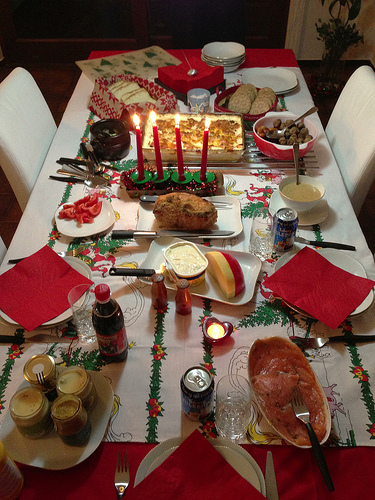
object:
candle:
[133, 115, 147, 182]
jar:
[9, 385, 51, 440]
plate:
[0, 362, 116, 469]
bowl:
[251, 110, 318, 161]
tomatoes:
[59, 206, 76, 219]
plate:
[54, 196, 116, 239]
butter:
[167, 243, 206, 276]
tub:
[163, 240, 209, 289]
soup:
[281, 182, 320, 203]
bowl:
[277, 174, 327, 213]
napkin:
[2, 245, 99, 329]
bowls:
[201, 38, 247, 60]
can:
[180, 365, 214, 425]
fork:
[290, 386, 334, 493]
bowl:
[246, 331, 331, 449]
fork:
[111, 451, 133, 500]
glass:
[215, 372, 254, 444]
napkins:
[156, 53, 226, 83]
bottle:
[92, 284, 128, 363]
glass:
[68, 282, 101, 347]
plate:
[133, 234, 265, 307]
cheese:
[203, 251, 247, 300]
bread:
[122, 89, 157, 104]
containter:
[88, 71, 180, 133]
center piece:
[120, 111, 223, 200]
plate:
[0, 257, 93, 328]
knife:
[109, 227, 236, 240]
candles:
[149, 122, 165, 181]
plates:
[240, 67, 300, 95]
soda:
[92, 299, 130, 362]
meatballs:
[289, 126, 298, 135]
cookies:
[228, 91, 252, 114]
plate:
[212, 83, 278, 121]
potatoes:
[250, 340, 326, 445]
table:
[1, 47, 374, 498]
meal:
[11, 73, 332, 450]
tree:
[233, 294, 300, 332]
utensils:
[56, 167, 108, 188]